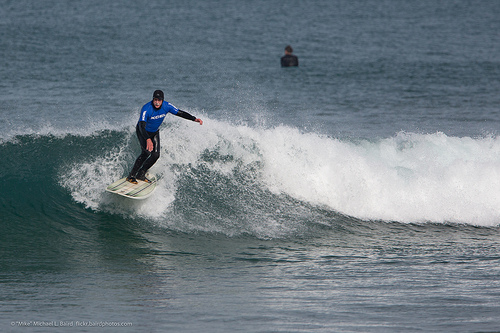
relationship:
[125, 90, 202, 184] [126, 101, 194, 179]
man wearing wet suit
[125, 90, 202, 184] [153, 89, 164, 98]
man wearing hat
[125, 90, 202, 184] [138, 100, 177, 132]
man wearing rash guard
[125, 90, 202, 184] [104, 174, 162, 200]
man on top of surfboard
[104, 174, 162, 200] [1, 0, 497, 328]
surfboard in water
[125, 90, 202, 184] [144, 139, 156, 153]
man has hand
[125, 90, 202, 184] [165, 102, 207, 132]
man has arm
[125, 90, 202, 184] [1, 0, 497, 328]
man on water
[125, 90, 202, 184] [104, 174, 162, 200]
man standing on surfboard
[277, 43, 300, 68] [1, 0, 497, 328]
man in water